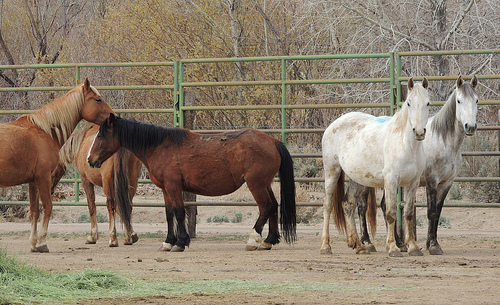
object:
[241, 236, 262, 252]
hoof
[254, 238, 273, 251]
hoof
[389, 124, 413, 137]
mark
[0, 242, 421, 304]
grass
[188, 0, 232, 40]
tree branch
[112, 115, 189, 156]
mane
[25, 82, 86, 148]
mane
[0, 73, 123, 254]
panel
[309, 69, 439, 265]
panel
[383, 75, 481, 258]
panel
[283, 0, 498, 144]
tree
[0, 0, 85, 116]
tree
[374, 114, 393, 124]
mark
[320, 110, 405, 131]
back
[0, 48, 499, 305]
corral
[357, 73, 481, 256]
horse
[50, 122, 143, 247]
horse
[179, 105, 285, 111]
pole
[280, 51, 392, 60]
pole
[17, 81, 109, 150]
mane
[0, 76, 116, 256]
horse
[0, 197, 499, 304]
floor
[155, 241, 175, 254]
hooves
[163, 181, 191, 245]
leg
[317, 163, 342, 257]
leg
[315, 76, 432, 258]
horse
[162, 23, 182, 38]
leaves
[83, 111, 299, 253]
horse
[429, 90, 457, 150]
mane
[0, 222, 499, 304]
dirt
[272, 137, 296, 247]
tail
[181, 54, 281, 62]
poles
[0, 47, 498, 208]
fence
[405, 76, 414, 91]
ear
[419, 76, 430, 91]
ear